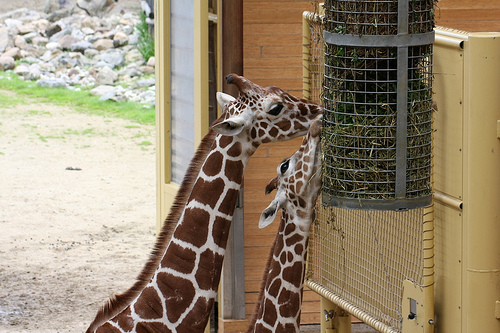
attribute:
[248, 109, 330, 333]
giraffe — smaller, reaching up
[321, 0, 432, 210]
basket — meshed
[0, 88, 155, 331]
ground — here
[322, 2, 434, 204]
container — here, metal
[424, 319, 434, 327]
bolt — here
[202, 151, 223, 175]
brown part — here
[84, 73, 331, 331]
giraffes — together, long necked, eating, young, white, brown, inside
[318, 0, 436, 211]
cage — here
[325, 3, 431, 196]
grass — here, green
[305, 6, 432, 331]
fence — metallic, yellow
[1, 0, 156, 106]
rocks — here, piled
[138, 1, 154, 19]
white line — here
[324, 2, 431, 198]
mesh — here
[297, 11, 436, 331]
frame — metal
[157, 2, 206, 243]
door — open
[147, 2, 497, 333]
building — lit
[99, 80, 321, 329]
giraffe — brown, white